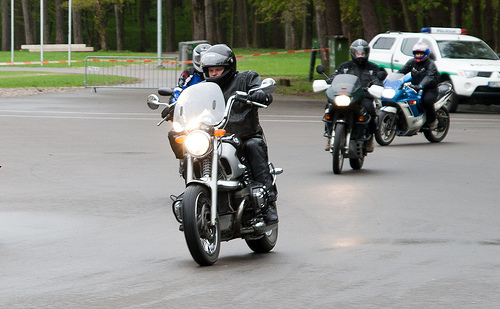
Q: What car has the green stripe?
A: The police car.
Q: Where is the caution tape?
A: In the distance.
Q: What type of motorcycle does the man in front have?
A: Silver and black motorcycle.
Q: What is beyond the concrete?
A: Grassy field.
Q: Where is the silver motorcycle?
A: On the street.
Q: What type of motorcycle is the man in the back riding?
A: Blue and silver.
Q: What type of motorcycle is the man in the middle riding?
A: Black motorcycle.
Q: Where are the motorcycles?
A: On the street.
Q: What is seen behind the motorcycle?
A: Police vehicle.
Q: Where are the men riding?
A: Motorcycle.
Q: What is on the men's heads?
A: Helmets.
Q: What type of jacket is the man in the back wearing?
A: Black leather jacket.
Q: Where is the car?
A: Behind the motorcycles.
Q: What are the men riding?
A: Motorcycles.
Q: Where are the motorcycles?
A: On the road.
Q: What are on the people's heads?
A: Helmets.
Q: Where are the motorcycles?
A: On the street.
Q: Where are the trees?
A: In the grass.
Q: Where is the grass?
A: Behind the road.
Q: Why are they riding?
A: To get somewhere.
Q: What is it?
A: Bikes.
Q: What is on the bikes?
A: People.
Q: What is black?
A: Helmet.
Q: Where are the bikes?
A: On the street.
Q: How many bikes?
A: 4.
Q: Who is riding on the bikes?
A: People.